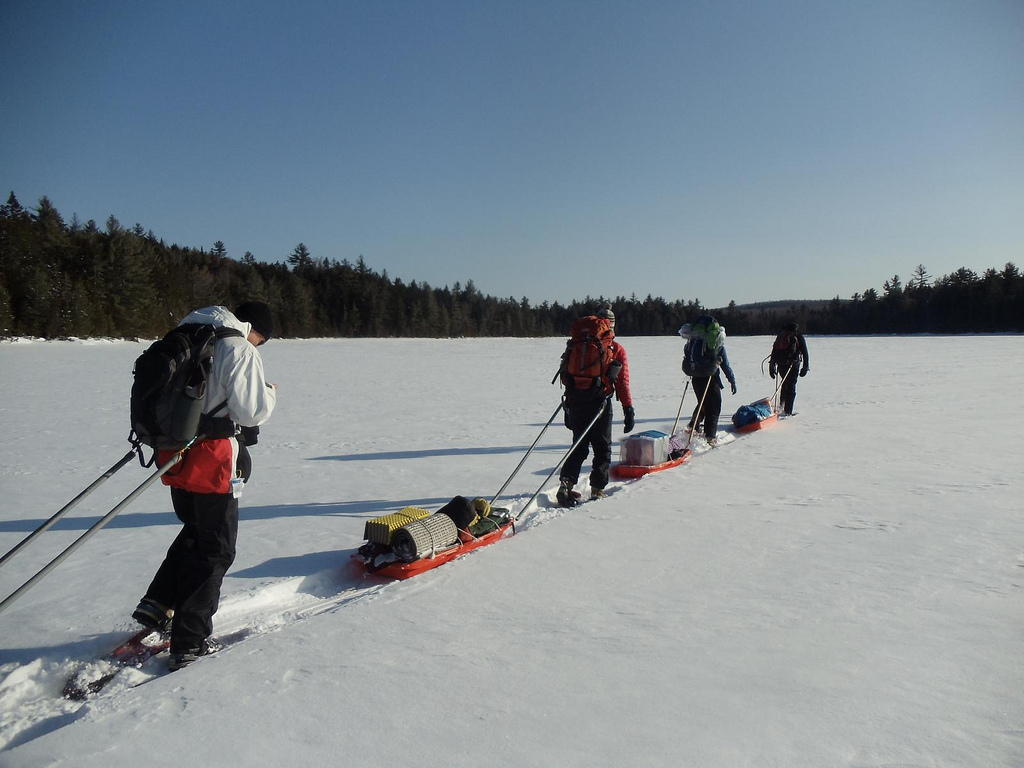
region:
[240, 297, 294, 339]
Person wearing black hat.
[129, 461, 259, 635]
Person wearing black pants.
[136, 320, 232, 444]
Back pack on person's back.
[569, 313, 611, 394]
Back pack on person's back.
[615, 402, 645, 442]
Person wearing black gloves.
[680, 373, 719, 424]
Person wearing black pants.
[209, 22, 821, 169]
Clear blue colored sky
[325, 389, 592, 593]
Man pulling on sledge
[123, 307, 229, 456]
Big packed black backpack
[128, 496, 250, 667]
Black wide warm pants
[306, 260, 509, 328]
Green colored bushy trees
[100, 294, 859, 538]
People on a straight line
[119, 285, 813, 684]
four people walking across snow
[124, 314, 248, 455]
back pack on person in white shirts back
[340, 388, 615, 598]
orange plastic pull cart on snow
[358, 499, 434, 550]
yellow package on back of orange cart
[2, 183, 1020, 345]
line of green trees lining snow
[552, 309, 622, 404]
orange back pack on person's back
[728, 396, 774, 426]
blue bag on back of orange surface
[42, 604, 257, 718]
pair of skis on person's feet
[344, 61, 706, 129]
blue and clear sky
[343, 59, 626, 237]
no clouds in sky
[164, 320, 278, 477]
man has white jacket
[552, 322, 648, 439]
man has orange jacket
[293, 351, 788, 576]
people carrying orange sleds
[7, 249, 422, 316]
tall and green trees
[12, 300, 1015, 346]
tall trees in distance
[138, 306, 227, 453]
man has black backpack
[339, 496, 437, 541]
yellow blanket on sled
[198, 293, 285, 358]
the head of a man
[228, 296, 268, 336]
the hat of a man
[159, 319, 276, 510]
the jacket of a man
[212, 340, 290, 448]
the arm of a man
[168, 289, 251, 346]
the hood of a man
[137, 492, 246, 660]
the pants of a man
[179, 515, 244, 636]
the leg of a man